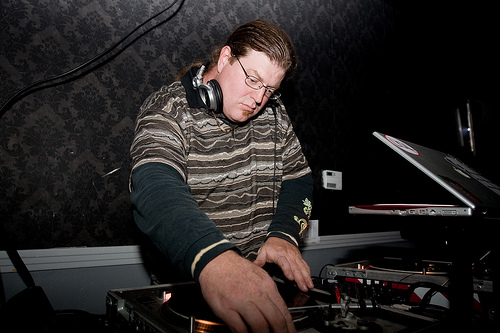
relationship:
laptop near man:
[341, 123, 484, 227] [123, 16, 336, 326]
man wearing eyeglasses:
[127, 18, 319, 333] [229, 47, 283, 100]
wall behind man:
[1, 1, 485, 273] [127, 18, 319, 333]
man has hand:
[127, 18, 319, 333] [194, 248, 301, 331]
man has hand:
[127, 18, 319, 333] [248, 234, 318, 294]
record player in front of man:
[102, 263, 420, 332] [123, 16, 336, 326]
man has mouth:
[123, 16, 336, 326] [235, 99, 260, 117]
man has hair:
[123, 16, 336, 326] [164, 15, 300, 86]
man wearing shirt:
[127, 18, 319, 333] [124, 76, 320, 266]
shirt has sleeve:
[124, 160, 322, 277] [123, 157, 245, 290]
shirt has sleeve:
[124, 160, 322, 277] [258, 166, 325, 253]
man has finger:
[127, 18, 319, 333] [262, 286, 297, 328]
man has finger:
[127, 18, 319, 333] [252, 291, 292, 331]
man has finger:
[127, 18, 319, 333] [253, 244, 271, 269]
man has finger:
[127, 18, 319, 333] [275, 254, 296, 283]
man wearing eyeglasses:
[127, 18, 319, 333] [231, 53, 281, 103]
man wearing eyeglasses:
[123, 16, 336, 326] [231, 53, 281, 103]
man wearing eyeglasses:
[123, 16, 336, 326] [229, 49, 285, 101]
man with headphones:
[123, 16, 336, 326] [178, 62, 223, 117]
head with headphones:
[195, 14, 296, 128] [178, 62, 223, 117]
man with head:
[123, 16, 336, 326] [195, 14, 296, 128]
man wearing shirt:
[123, 16, 336, 326] [128, 74, 328, 273]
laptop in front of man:
[346, 130, 500, 218] [123, 16, 336, 326]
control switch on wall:
[310, 153, 356, 196] [323, 22, 403, 198]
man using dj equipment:
[123, 16, 336, 326] [236, 120, 496, 329]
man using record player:
[127, 18, 319, 333] [176, 257, 453, 330]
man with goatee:
[127, 18, 319, 333] [229, 99, 267, 125]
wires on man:
[314, 257, 439, 322] [127, 18, 319, 333]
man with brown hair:
[127, 18, 319, 333] [233, 14, 296, 70]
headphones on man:
[165, 55, 245, 120] [114, 28, 352, 270]